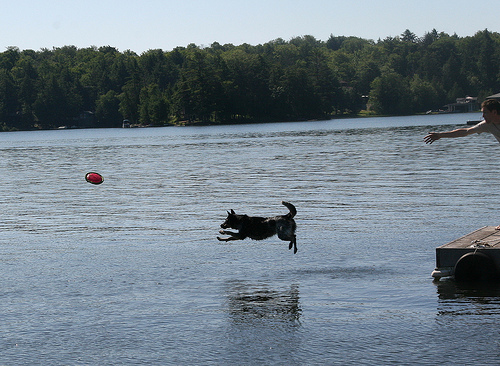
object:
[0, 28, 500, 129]
line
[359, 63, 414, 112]
tree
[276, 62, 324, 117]
tree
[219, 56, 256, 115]
tree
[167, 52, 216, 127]
tree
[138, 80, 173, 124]
tree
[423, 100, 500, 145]
person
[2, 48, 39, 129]
trees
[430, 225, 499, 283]
brown dock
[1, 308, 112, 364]
water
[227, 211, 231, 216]
dog ears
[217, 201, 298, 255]
dog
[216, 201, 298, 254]
black body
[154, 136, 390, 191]
lake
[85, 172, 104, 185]
ball